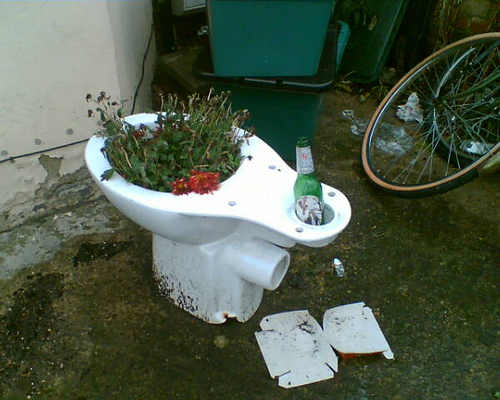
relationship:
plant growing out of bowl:
[84, 86, 257, 196] [101, 120, 247, 192]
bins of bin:
[192, 0, 352, 165] [228, 16, 354, 147]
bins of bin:
[229, 27, 359, 145] [206, 1, 339, 80]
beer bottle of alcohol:
[291, 135, 325, 226] [290, 129, 340, 229]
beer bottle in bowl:
[291, 135, 325, 226] [106, 107, 239, 197]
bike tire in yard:
[350, 25, 496, 198] [5, 65, 493, 395]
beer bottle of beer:
[291, 135, 325, 226] [296, 189, 323, 227]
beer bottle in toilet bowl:
[291, 135, 325, 226] [81, 102, 352, 327]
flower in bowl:
[172, 166, 222, 196] [101, 120, 247, 192]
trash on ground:
[252, 294, 496, 378] [295, 264, 479, 394]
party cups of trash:
[251, 301, 398, 390] [252, 294, 496, 378]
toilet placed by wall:
[81, 109, 353, 325] [12, 21, 176, 158]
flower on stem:
[98, 90, 108, 100] [104, 117, 136, 170]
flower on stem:
[156, 87, 166, 97] [156, 98, 166, 138]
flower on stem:
[244, 120, 254, 145] [221, 134, 242, 167]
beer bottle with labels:
[291, 135, 325, 226] [297, 144, 320, 221]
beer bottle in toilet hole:
[291, 135, 325, 226] [293, 196, 333, 230]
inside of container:
[273, 320, 318, 369] [256, 299, 407, 391]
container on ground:
[256, 299, 407, 391] [5, 94, 498, 397]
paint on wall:
[0, 0, 111, 221] [2, 1, 153, 272]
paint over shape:
[0, 0, 111, 221] [72, 240, 133, 272]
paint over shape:
[0, 0, 111, 221] [4, 269, 69, 354]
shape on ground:
[72, 240, 133, 272] [0, 7, 496, 399]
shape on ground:
[4, 269, 69, 354] [0, 7, 496, 399]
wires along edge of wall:
[1, 22, 156, 163] [1, 0, 157, 236]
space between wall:
[149, 0, 211, 77] [2, 1, 153, 272]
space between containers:
[149, 0, 211, 77] [207, 0, 410, 89]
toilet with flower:
[65, 96, 372, 351] [168, 177, 190, 199]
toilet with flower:
[65, 96, 372, 351] [187, 166, 220, 194]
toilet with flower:
[65, 96, 372, 351] [96, 84, 133, 170]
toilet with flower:
[65, 96, 372, 351] [137, 120, 162, 152]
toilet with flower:
[65, 96, 372, 351] [211, 100, 252, 154]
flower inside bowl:
[168, 177, 190, 199] [101, 120, 247, 192]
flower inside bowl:
[187, 166, 220, 194] [101, 120, 247, 192]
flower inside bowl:
[96, 84, 133, 170] [101, 120, 247, 192]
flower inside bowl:
[137, 120, 162, 152] [101, 120, 247, 192]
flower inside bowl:
[211, 100, 252, 154] [101, 120, 247, 192]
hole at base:
[72, 237, 132, 264] [0, 194, 132, 326]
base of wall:
[0, 194, 132, 326] [7, 7, 160, 224]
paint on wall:
[0, 0, 111, 221] [5, 3, 169, 286]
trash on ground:
[400, 100, 430, 127] [374, 203, 472, 274]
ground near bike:
[374, 203, 472, 274] [358, 106, 441, 203]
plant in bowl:
[79, 82, 257, 198] [99, 117, 262, 193]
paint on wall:
[0, 117, 111, 221] [0, 1, 190, 281]